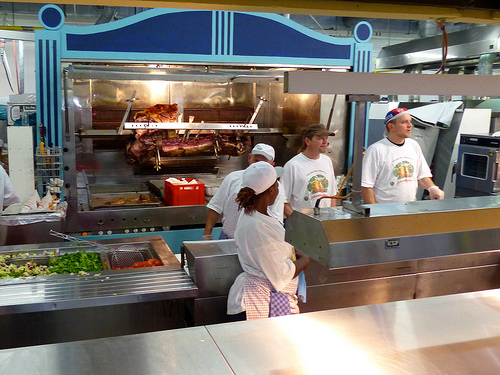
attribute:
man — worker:
[353, 92, 451, 208]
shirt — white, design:
[378, 145, 417, 207]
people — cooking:
[186, 118, 426, 281]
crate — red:
[172, 181, 202, 204]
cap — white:
[299, 122, 327, 137]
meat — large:
[111, 197, 148, 201]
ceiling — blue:
[150, 26, 205, 48]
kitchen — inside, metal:
[1, 49, 421, 321]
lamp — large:
[127, 70, 169, 93]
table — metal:
[415, 215, 482, 248]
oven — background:
[121, 108, 228, 147]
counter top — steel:
[478, 203, 487, 245]